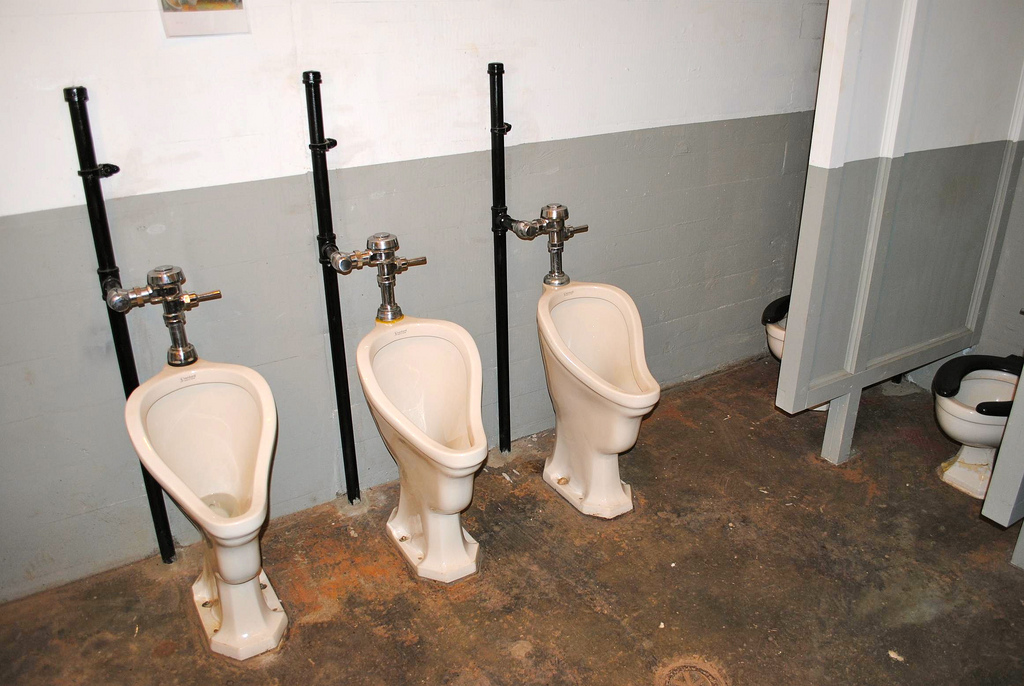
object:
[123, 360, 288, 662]
urinal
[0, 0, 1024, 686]
restroom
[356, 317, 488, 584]
urinal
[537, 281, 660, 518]
urinal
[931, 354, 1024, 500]
toilet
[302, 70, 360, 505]
pipe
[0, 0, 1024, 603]
wall